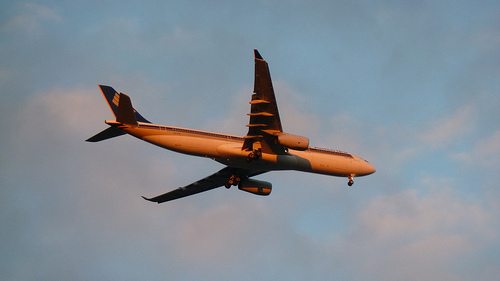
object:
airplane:
[84, 49, 377, 205]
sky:
[0, 0, 500, 281]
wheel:
[348, 180, 355, 187]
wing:
[119, 92, 138, 124]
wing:
[84, 126, 127, 143]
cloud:
[39, 91, 179, 185]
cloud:
[317, 185, 496, 280]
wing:
[248, 47, 283, 144]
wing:
[141, 166, 246, 204]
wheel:
[246, 152, 258, 162]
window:
[173, 127, 176, 130]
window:
[185, 129, 188, 133]